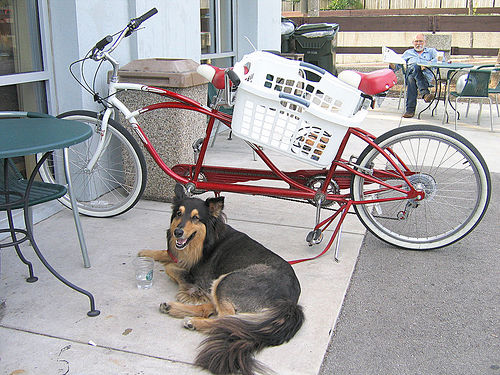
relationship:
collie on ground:
[137, 182, 305, 362] [65, 207, 192, 373]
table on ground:
[5, 99, 115, 236] [0, 55, 500, 374]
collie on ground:
[162, 192, 283, 363] [121, 282, 161, 349]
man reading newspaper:
[386, 32, 446, 120] [377, 40, 410, 67]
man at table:
[389, 34, 446, 117] [412, 53, 481, 133]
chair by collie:
[2, 147, 72, 246] [137, 182, 305, 362]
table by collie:
[0, 117, 100, 316] [137, 182, 305, 362]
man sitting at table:
[389, 34, 446, 117] [387, 64, 477, 119]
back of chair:
[462, 56, 482, 101] [454, 53, 490, 103]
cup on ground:
[131, 251, 169, 292] [6, 96, 496, 369]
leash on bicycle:
[287, 195, 352, 285] [34, 6, 493, 262]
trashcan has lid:
[109, 44, 220, 204] [119, 32, 215, 92]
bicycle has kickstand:
[34, 6, 493, 262] [327, 200, 354, 274]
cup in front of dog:
[132, 256, 155, 289] [109, 172, 309, 335]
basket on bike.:
[234, 39, 376, 170] [40, 15, 498, 280]